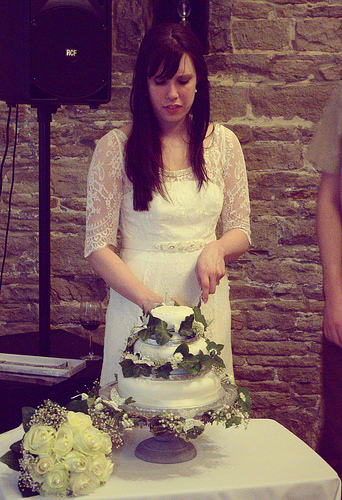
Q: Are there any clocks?
A: No, there are no clocks.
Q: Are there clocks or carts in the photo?
A: No, there are no clocks or carts.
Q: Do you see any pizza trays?
A: No, there are no pizza trays.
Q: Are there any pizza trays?
A: No, there are no pizza trays.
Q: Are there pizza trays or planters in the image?
A: No, there are no pizza trays or planters.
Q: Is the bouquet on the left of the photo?
A: Yes, the bouquet is on the left of the image.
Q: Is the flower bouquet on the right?
A: No, the flower bouquet is on the left of the image.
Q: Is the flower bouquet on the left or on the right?
A: The flower bouquet is on the left of the image.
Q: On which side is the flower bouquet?
A: The flower bouquet is on the left of the image.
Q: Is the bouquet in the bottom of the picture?
A: Yes, the bouquet is in the bottom of the image.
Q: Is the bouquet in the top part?
A: No, the bouquet is in the bottom of the image.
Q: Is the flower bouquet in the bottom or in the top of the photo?
A: The flower bouquet is in the bottom of the image.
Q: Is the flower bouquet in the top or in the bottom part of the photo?
A: The flower bouquet is in the bottom of the image.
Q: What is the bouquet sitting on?
A: The bouquet is sitting on the table.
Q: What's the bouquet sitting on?
A: The bouquet is sitting on the table.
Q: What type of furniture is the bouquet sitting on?
A: The bouquet is sitting on the table.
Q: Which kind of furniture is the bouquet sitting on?
A: The bouquet is sitting on the table.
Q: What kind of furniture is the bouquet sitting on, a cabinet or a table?
A: The bouquet is sitting on a table.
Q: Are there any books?
A: No, there are no books.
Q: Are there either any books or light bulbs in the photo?
A: No, there are no books or light bulbs.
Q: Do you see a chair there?
A: No, there are no chairs.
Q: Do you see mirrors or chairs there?
A: No, there are no chairs or mirrors.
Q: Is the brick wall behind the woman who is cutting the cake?
A: Yes, the wall is behind the woman.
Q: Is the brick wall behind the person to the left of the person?
A: Yes, the wall is behind the woman.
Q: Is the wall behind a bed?
A: No, the wall is behind the woman.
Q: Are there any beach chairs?
A: No, there are no beach chairs.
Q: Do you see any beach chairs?
A: No, there are no beach chairs.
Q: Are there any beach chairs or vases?
A: No, there are no beach chairs or vases.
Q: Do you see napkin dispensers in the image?
A: No, there are no napkin dispensers.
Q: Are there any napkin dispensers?
A: No, there are no napkin dispensers.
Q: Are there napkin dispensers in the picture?
A: No, there are no napkin dispensers.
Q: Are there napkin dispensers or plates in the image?
A: No, there are no napkin dispensers or plates.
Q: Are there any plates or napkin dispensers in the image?
A: No, there are no napkin dispensers or plates.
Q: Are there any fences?
A: No, there are no fences.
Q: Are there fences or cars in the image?
A: No, there are no fences or cars.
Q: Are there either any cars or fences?
A: No, there are no fences or cars.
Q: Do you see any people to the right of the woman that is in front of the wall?
A: Yes, there is a person to the right of the woman.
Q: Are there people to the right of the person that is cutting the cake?
A: Yes, there is a person to the right of the woman.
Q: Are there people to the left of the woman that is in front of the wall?
A: No, the person is to the right of the woman.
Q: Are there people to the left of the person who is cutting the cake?
A: No, the person is to the right of the woman.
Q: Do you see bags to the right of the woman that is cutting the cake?
A: No, there is a person to the right of the woman.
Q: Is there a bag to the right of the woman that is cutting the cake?
A: No, there is a person to the right of the woman.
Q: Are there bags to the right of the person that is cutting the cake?
A: No, there is a person to the right of the woman.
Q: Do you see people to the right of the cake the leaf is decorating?
A: Yes, there is a person to the right of the cake.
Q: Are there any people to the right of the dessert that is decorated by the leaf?
A: Yes, there is a person to the right of the cake.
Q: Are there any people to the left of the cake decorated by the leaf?
A: No, the person is to the right of the cake.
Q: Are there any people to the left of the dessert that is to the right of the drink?
A: No, the person is to the right of the cake.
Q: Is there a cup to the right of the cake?
A: No, there is a person to the right of the cake.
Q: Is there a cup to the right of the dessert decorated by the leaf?
A: No, there is a person to the right of the cake.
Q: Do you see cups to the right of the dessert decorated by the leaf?
A: No, there is a person to the right of the cake.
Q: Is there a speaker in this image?
A: Yes, there is a speaker.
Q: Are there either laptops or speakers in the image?
A: Yes, there is a speaker.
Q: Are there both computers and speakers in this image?
A: No, there is a speaker but no computers.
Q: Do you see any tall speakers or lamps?
A: Yes, there is a tall speaker.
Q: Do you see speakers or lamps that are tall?
A: Yes, the speaker is tall.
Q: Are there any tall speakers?
A: Yes, there is a tall speaker.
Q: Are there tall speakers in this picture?
A: Yes, there is a tall speaker.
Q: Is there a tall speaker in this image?
A: Yes, there is a tall speaker.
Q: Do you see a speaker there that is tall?
A: Yes, there is a speaker that is tall.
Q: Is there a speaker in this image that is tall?
A: Yes, there is a speaker that is tall.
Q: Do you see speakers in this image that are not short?
A: Yes, there is a tall speaker.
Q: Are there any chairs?
A: No, there are no chairs.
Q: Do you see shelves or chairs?
A: No, there are no chairs or shelves.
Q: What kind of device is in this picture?
A: The device is a speaker.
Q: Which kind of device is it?
A: The device is a speaker.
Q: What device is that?
A: This is a speaker.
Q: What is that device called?
A: This is a speaker.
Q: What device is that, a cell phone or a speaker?
A: This is a speaker.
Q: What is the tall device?
A: The device is a speaker.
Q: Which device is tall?
A: The device is a speaker.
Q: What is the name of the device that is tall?
A: The device is a speaker.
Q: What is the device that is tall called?
A: The device is a speaker.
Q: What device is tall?
A: The device is a speaker.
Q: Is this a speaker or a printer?
A: This is a speaker.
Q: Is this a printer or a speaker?
A: This is a speaker.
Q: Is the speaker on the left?
A: Yes, the speaker is on the left of the image.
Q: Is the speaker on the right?
A: No, the speaker is on the left of the image.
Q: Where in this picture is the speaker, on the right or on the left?
A: The speaker is on the left of the image.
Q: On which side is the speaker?
A: The speaker is on the left of the image.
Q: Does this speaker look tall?
A: Yes, the speaker is tall.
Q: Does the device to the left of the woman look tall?
A: Yes, the speaker is tall.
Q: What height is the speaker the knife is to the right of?
A: The speaker is tall.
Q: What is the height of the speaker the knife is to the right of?
A: The speaker is tall.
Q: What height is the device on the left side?
A: The speaker is tall.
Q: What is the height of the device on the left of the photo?
A: The speaker is tall.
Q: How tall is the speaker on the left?
A: The speaker is tall.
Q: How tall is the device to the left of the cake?
A: The speaker is tall.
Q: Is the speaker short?
A: No, the speaker is tall.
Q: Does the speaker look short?
A: No, the speaker is tall.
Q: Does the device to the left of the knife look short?
A: No, the speaker is tall.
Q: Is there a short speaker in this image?
A: No, there is a speaker but it is tall.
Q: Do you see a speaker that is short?
A: No, there is a speaker but it is tall.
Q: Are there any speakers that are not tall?
A: No, there is a speaker but it is tall.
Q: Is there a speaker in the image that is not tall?
A: No, there is a speaker but it is tall.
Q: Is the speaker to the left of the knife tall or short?
A: The speaker is tall.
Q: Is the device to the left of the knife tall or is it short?
A: The speaker is tall.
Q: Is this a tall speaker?
A: Yes, this is a tall speaker.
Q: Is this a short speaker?
A: No, this is a tall speaker.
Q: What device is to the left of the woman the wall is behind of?
A: The device is a speaker.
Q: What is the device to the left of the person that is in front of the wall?
A: The device is a speaker.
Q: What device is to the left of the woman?
A: The device is a speaker.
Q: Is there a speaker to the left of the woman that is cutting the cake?
A: Yes, there is a speaker to the left of the woman.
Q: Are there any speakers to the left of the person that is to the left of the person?
A: Yes, there is a speaker to the left of the woman.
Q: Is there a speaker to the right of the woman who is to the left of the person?
A: No, the speaker is to the left of the woman.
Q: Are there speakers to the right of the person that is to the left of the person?
A: No, the speaker is to the left of the woman.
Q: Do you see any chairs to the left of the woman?
A: No, there is a speaker to the left of the woman.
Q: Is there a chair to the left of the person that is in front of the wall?
A: No, there is a speaker to the left of the woman.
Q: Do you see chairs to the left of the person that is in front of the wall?
A: No, there is a speaker to the left of the woman.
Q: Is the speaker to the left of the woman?
A: Yes, the speaker is to the left of the woman.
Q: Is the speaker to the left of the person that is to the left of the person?
A: Yes, the speaker is to the left of the woman.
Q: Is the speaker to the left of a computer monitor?
A: No, the speaker is to the left of the woman.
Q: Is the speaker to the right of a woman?
A: No, the speaker is to the left of a woman.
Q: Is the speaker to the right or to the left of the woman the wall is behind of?
A: The speaker is to the left of the woman.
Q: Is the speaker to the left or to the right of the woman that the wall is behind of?
A: The speaker is to the left of the woman.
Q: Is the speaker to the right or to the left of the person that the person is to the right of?
A: The speaker is to the left of the woman.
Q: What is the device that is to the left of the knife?
A: The device is a speaker.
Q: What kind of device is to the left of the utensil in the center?
A: The device is a speaker.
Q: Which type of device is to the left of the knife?
A: The device is a speaker.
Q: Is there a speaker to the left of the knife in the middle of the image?
A: Yes, there is a speaker to the left of the knife.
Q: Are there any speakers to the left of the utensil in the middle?
A: Yes, there is a speaker to the left of the knife.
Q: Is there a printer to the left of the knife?
A: No, there is a speaker to the left of the knife.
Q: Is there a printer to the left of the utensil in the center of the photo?
A: No, there is a speaker to the left of the knife.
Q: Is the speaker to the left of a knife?
A: Yes, the speaker is to the left of a knife.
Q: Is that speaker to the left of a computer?
A: No, the speaker is to the left of a knife.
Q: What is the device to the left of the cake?
A: The device is a speaker.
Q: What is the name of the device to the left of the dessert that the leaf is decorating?
A: The device is a speaker.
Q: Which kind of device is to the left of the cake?
A: The device is a speaker.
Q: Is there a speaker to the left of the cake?
A: Yes, there is a speaker to the left of the cake.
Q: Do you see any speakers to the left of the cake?
A: Yes, there is a speaker to the left of the cake.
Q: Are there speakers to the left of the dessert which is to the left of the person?
A: Yes, there is a speaker to the left of the cake.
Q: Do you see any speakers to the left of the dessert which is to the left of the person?
A: Yes, there is a speaker to the left of the cake.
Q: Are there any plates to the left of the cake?
A: No, there is a speaker to the left of the cake.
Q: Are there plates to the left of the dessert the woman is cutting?
A: No, there is a speaker to the left of the cake.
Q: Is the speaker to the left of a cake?
A: Yes, the speaker is to the left of a cake.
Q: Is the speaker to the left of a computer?
A: No, the speaker is to the left of a cake.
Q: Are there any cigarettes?
A: No, there are no cigarettes.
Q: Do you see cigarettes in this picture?
A: No, there are no cigarettes.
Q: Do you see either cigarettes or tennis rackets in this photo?
A: No, there are no cigarettes or tennis rackets.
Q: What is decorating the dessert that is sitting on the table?
A: The leaf is decorating the cake.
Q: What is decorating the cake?
A: The leaf is decorating the cake.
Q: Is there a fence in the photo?
A: No, there are no fences.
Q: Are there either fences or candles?
A: No, there are no fences or candles.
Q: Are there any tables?
A: Yes, there is a table.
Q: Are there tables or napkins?
A: Yes, there is a table.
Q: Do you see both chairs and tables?
A: No, there is a table but no chairs.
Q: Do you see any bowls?
A: No, there are no bowls.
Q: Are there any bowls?
A: No, there are no bowls.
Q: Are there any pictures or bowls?
A: No, there are no bowls or pictures.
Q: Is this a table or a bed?
A: This is a table.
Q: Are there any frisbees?
A: No, there are no frisbees.